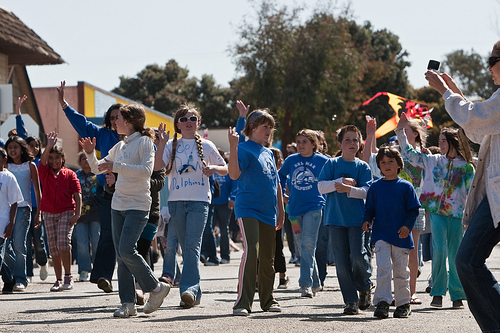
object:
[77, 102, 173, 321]
child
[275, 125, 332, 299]
girl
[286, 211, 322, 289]
blue pants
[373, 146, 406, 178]
hair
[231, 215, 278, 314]
pants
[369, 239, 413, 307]
white pants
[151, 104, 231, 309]
girl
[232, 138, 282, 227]
shirt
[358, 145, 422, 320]
boy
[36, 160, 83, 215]
shirt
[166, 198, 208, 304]
jeans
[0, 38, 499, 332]
parade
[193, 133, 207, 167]
pigtails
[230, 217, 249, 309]
stripe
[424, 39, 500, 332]
woman